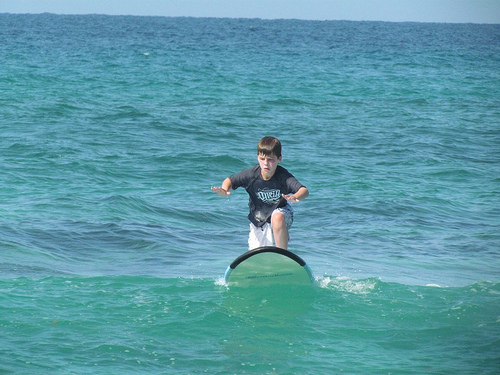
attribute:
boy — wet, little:
[211, 134, 311, 252]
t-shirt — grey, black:
[226, 166, 308, 230]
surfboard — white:
[222, 245, 319, 291]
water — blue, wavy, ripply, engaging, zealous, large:
[1, 15, 499, 375]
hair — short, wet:
[256, 134, 285, 159]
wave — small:
[2, 267, 499, 324]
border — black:
[228, 245, 312, 272]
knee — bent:
[269, 209, 291, 227]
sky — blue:
[3, 1, 500, 26]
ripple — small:
[87, 218, 163, 241]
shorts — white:
[246, 204, 293, 252]